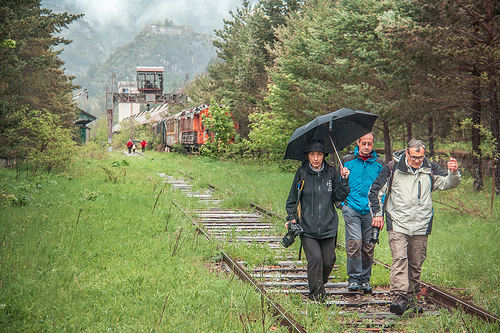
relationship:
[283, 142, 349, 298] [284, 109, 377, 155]
woman holding umbrella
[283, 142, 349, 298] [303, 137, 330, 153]
woman wearing hat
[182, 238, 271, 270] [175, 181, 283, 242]
grass covering track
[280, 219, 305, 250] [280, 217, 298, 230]
camera in hand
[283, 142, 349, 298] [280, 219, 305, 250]
woman carrying camera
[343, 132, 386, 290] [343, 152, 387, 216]
man wearing jacket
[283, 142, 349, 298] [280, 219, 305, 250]
woman holding camera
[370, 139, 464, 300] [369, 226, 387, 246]
man holding camera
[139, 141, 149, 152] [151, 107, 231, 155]
person near train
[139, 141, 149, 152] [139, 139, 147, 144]
person wearing red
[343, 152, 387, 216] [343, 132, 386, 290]
jacket on man